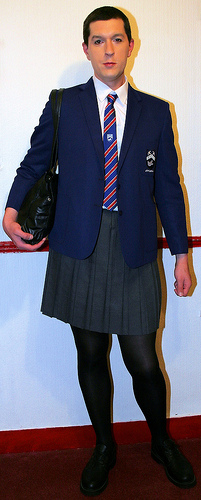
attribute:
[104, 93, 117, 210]
tie — red, blue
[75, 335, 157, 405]
tights — black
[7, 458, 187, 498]
floor — red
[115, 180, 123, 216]
buttons — black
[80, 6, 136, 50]
hair — dark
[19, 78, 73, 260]
leather purse — black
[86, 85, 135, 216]
tie — red, blue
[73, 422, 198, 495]
black shoes — dress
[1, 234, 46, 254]
crown — red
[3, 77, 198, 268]
jacket — blue